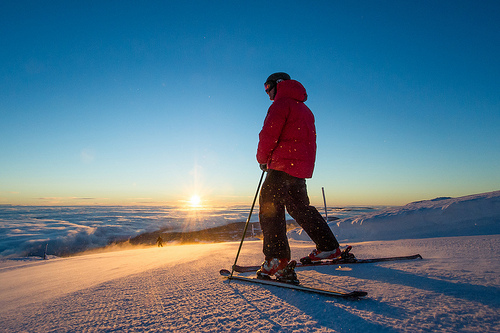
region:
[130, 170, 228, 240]
shining sun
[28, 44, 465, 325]
clear sunny day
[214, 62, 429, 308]
man wearing warm ski clothes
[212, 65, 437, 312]
man wearing snow pants and downhill skis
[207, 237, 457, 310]
downhill skis in pie position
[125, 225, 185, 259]
person skiing down mountain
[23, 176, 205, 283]
view from mountaintop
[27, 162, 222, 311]
sky, sun, and snow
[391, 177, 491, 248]
snow on mountain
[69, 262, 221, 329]
snow on ski slope that has been recently groomed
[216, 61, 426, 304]
a man wearing skis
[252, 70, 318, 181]
a man wearing a red coat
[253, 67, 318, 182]
a man with a black helmet wearing a red coat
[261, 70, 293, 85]
a black helmet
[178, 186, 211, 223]
the sun can be seen in the background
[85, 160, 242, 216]
an image of the sunrise can be seen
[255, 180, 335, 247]
black pants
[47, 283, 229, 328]
tracks in the snow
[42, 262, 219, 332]
snow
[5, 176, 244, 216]
a skyline can be seen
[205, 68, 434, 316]
A MAN STANDING ON A SKI SLOPE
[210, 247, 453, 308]
A PAIR OF SKIS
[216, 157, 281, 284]
A SKI POLE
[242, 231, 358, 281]
A PAIR OF SKI SHOES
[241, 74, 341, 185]
A MAN'S RED JACKET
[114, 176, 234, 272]
THE SUN SETTING IN THE DISTANCE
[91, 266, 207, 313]
SNOW ON THE GROUND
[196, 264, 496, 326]
A SHADOW ON THE SNOW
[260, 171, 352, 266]
A PAIR OF BLACK SKI PANTS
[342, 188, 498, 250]
A MOUND OF SNOW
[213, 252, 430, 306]
The skis the man is wearing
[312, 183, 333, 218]
a pole by the hill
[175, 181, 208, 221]
the shining sun during the day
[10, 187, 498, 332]
a mountain covered in snow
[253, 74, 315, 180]
the red jacket the man is wearing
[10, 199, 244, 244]
what looks like more hills in the background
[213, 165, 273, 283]
the ski pole in the man's hand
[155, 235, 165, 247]
another person on the mountain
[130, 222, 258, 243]
a plain part of the hill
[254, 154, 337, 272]
the dark part of the man's pants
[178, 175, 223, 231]
Bright sun on the horizon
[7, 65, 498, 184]
Bright blue clear sky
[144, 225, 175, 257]
Skier in the distance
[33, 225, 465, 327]
Ski slope reflecting sunlight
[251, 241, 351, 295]
orange and white ski boots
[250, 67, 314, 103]
Skier wearing protective head gear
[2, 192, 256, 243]
White fluffy clouds in the distance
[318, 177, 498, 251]
Hard packed snow walls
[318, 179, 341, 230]
marker for side of ski slope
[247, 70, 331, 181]
Skier wearing warm jacket